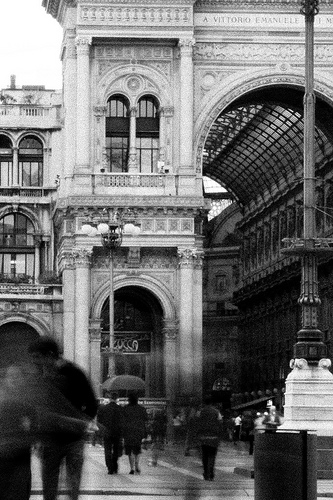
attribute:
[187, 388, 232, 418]
umbrella — black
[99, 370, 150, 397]
umbrella — black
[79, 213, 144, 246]
umbrella — vblack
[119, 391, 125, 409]
rod — thin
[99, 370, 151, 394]
umbrella — open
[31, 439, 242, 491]
ground — wet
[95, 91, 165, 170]
windows — arched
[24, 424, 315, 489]
street — wet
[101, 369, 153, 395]
umbrella — dark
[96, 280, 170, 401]
entryway — arched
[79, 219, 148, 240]
globes — white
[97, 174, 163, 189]
railing — stone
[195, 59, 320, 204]
beams — curved, support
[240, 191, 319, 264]
medallions — ornate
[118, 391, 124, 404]
rod — thin, umbrella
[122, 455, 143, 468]
skin — exposed